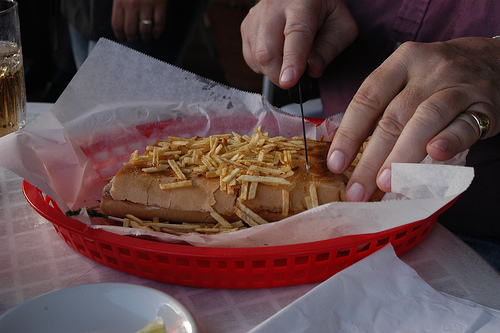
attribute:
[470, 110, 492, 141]
ring — gold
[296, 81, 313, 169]
knife — cutting, silver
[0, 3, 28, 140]
glass — clear, half full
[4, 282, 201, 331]
bowl — white, round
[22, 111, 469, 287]
basket — red, plastic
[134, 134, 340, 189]
fries — brown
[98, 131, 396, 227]
food — brown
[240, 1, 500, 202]
person — cutting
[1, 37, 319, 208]
paper — white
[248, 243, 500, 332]
napkin — white, paper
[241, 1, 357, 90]
fingers — short